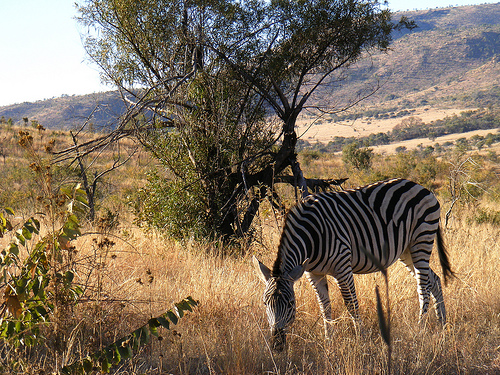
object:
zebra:
[250, 176, 461, 353]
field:
[0, 132, 500, 374]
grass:
[112, 235, 249, 312]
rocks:
[376, 66, 446, 92]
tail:
[433, 227, 463, 284]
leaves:
[37, 205, 88, 259]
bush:
[0, 188, 198, 374]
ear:
[252, 255, 276, 288]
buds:
[357, 247, 400, 374]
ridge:
[389, 2, 500, 27]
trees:
[74, 0, 421, 256]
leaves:
[182, 44, 273, 129]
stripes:
[315, 221, 390, 255]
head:
[263, 277, 294, 351]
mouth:
[269, 332, 287, 352]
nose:
[265, 328, 284, 346]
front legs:
[310, 276, 363, 345]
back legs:
[401, 245, 449, 330]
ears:
[251, 254, 307, 280]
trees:
[326, 102, 405, 117]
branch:
[201, 38, 295, 114]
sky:
[0, 2, 500, 108]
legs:
[305, 231, 446, 341]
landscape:
[0, 82, 500, 373]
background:
[0, 0, 500, 138]